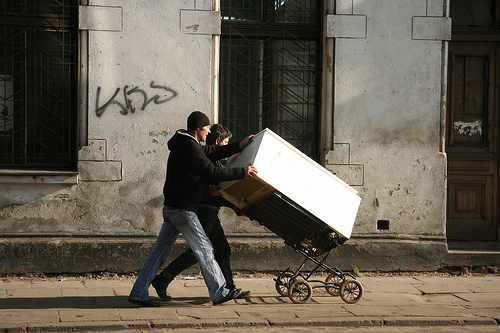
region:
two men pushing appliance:
[130, 110, 245, 310]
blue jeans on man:
[131, 196, 221, 303]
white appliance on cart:
[260, 130, 362, 255]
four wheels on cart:
[275, 264, 375, 306]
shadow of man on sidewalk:
[22, 286, 135, 318]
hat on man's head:
[180, 107, 215, 137]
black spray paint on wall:
[85, 72, 185, 127]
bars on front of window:
[237, 27, 314, 114]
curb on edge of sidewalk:
[380, 313, 453, 331]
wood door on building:
[443, 38, 494, 237]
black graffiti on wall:
[78, 61, 198, 123]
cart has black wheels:
[270, 267, 352, 299]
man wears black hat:
[185, 107, 216, 130]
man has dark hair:
[207, 123, 234, 148]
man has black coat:
[167, 127, 207, 204]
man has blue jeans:
[166, 203, 237, 298]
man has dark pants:
[177, 213, 234, 293]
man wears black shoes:
[217, 286, 240, 306]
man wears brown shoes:
[233, 288, 254, 303]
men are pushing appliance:
[223, 113, 363, 266]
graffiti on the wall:
[92, 80, 177, 114]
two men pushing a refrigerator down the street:
[132, 105, 360, 308]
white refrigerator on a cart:
[222, 129, 361, 302]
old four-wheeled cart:
[275, 233, 362, 303]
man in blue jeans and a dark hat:
[130, 107, 255, 306]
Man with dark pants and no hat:
[152, 122, 250, 299]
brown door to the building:
[449, 6, 498, 248]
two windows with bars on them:
[2, 2, 324, 174]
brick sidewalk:
[4, 276, 497, 321]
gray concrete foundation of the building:
[1, 238, 496, 274]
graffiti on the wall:
[88, 75, 198, 135]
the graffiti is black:
[95, 68, 181, 149]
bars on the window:
[220, 13, 319, 160]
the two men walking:
[153, 114, 255, 318]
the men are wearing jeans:
[148, 216, 253, 328]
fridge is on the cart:
[228, 135, 393, 300]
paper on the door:
[450, 106, 496, 156]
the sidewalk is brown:
[366, 274, 447, 329]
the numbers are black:
[452, 115, 491, 130]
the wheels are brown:
[270, 275, 396, 325]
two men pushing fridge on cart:
[124, 110, 366, 310]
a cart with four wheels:
[271, 234, 364, 305]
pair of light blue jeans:
[122, 208, 234, 304]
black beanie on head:
[186, 110, 210, 132]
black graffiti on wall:
[92, 78, 179, 119]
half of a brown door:
[445, 25, 498, 246]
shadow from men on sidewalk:
[0, 293, 180, 310]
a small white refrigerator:
[223, 130, 363, 240]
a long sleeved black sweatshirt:
[160, 131, 245, 211]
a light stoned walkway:
[5, 268, 497, 330]